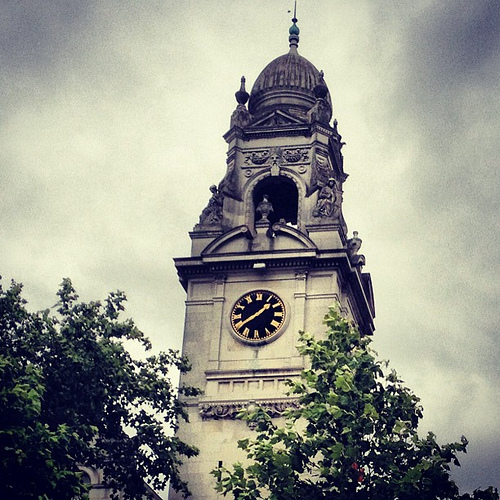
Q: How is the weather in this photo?
A: It is cloudy.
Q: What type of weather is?
A: It is cloudy.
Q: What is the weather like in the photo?
A: It is cloudy.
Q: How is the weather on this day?
A: It is cloudy.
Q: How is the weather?
A: It is cloudy.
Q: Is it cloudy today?
A: Yes, it is cloudy.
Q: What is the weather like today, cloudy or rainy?
A: It is cloudy.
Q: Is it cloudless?
A: No, it is cloudy.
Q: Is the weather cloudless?
A: No, it is cloudy.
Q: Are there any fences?
A: No, there are no fences.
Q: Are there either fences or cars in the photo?
A: No, there are no fences or cars.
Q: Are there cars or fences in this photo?
A: No, there are no fences or cars.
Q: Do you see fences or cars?
A: No, there are no fences or cars.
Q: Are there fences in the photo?
A: No, there are no fences.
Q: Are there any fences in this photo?
A: No, there are no fences.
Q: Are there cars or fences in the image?
A: No, there are no fences or cars.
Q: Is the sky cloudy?
A: Yes, the sky is cloudy.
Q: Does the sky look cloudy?
A: Yes, the sky is cloudy.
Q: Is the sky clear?
A: No, the sky is cloudy.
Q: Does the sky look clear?
A: No, the sky is cloudy.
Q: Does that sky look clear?
A: No, the sky is cloudy.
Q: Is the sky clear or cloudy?
A: The sky is cloudy.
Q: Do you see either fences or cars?
A: No, there are no fences or cars.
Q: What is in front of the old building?
A: The tree is in front of the clock tower.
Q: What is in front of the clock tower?
A: The tree is in front of the clock tower.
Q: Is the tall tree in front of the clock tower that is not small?
A: Yes, the tree is in front of the clock tower.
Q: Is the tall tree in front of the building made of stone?
A: Yes, the tree is in front of the clock tower.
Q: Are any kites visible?
A: No, there are no kites.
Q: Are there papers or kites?
A: No, there are no kites or papers.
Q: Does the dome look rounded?
A: Yes, the dome is rounded.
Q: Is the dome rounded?
A: Yes, the dome is rounded.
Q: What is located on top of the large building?
A: The dome is on top of the clock tower.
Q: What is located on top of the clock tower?
A: The dome is on top of the clock tower.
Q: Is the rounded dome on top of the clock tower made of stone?
A: Yes, the dome is on top of the clock tower.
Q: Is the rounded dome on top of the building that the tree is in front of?
A: Yes, the dome is on top of the clock tower.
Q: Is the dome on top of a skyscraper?
A: No, the dome is on top of the clock tower.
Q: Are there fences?
A: No, there are no fences.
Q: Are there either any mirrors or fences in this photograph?
A: No, there are no fences or mirrors.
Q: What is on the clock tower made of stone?
A: The statue is on the clock tower.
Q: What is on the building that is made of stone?
A: The statue is on the clock tower.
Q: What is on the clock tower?
A: The statue is on the clock tower.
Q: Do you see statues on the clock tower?
A: Yes, there is a statue on the clock tower.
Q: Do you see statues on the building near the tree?
A: Yes, there is a statue on the clock tower.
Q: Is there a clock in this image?
A: Yes, there is a clock.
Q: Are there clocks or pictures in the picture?
A: Yes, there is a clock.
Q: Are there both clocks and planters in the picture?
A: No, there is a clock but no planters.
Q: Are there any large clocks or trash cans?
A: Yes, there is a large clock.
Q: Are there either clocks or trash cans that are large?
A: Yes, the clock is large.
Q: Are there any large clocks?
A: Yes, there is a large clock.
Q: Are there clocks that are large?
A: Yes, there is a clock that is large.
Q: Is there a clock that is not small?
A: Yes, there is a large clock.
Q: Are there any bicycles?
A: No, there are no bicycles.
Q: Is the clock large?
A: Yes, the clock is large.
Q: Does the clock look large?
A: Yes, the clock is large.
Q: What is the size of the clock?
A: The clock is large.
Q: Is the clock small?
A: No, the clock is large.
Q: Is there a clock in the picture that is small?
A: No, there is a clock but it is large.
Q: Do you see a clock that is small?
A: No, there is a clock but it is large.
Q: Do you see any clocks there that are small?
A: No, there is a clock but it is large.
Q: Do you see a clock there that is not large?
A: No, there is a clock but it is large.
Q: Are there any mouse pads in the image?
A: No, there are no mouse pads.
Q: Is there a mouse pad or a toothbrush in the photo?
A: No, there are no mouse pads or toothbrushes.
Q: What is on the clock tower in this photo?
A: The statue is on the clock tower.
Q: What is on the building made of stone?
A: The statue is on the clock tower.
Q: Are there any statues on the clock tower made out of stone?
A: Yes, there is a statue on the clock tower.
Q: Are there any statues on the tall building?
A: Yes, there is a statue on the clock tower.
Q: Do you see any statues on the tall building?
A: Yes, there is a statue on the clock tower.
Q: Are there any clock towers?
A: Yes, there is a clock tower.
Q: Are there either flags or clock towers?
A: Yes, there is a clock tower.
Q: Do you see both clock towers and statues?
A: Yes, there are both a clock tower and a statue.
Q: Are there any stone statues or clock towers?
A: Yes, there is a stone clock tower.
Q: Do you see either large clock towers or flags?
A: Yes, there is a large clock tower.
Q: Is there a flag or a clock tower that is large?
A: Yes, the clock tower is large.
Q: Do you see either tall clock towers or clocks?
A: Yes, there is a tall clock tower.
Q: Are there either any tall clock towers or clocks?
A: Yes, there is a tall clock tower.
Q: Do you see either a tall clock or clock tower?
A: Yes, there is a tall clock tower.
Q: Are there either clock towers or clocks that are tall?
A: Yes, the clock tower is tall.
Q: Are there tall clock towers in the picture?
A: Yes, there is a tall clock tower.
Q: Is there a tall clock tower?
A: Yes, there is a tall clock tower.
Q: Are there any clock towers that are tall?
A: Yes, there is a clock tower that is tall.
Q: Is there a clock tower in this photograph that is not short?
A: Yes, there is a tall clock tower.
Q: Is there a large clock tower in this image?
A: Yes, there is a large clock tower.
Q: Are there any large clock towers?
A: Yes, there is a large clock tower.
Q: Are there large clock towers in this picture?
A: Yes, there is a large clock tower.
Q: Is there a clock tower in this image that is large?
A: Yes, there is a large clock tower.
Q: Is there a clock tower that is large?
A: Yes, there is a clock tower that is large.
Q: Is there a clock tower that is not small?
A: Yes, there is a large clock tower.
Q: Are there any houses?
A: No, there are no houses.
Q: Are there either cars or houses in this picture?
A: No, there are no houses or cars.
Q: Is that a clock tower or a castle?
A: That is a clock tower.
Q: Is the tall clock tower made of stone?
A: Yes, the clock tower is made of stone.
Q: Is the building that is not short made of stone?
A: Yes, the clock tower is made of stone.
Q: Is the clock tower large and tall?
A: Yes, the clock tower is large and tall.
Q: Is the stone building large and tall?
A: Yes, the clock tower is large and tall.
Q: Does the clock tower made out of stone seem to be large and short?
A: No, the clock tower is large but tall.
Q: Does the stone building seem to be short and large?
A: No, the clock tower is large but tall.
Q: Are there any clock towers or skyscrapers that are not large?
A: No, there is a clock tower but it is large.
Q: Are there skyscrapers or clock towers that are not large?
A: No, there is a clock tower but it is large.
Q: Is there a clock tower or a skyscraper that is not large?
A: No, there is a clock tower but it is large.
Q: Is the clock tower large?
A: Yes, the clock tower is large.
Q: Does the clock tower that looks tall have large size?
A: Yes, the clock tower is large.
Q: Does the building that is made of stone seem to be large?
A: Yes, the clock tower is large.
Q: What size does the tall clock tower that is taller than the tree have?
A: The clock tower has large size.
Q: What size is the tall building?
A: The clock tower is large.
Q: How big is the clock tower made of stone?
A: The clock tower is large.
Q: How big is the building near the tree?
A: The clock tower is large.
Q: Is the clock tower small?
A: No, the clock tower is large.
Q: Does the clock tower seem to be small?
A: No, the clock tower is large.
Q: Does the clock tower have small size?
A: No, the clock tower is large.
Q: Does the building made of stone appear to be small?
A: No, the clock tower is large.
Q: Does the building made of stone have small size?
A: No, the clock tower is large.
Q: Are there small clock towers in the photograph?
A: No, there is a clock tower but it is large.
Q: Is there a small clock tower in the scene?
A: No, there is a clock tower but it is large.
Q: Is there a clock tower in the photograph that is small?
A: No, there is a clock tower but it is large.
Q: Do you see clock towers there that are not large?
A: No, there is a clock tower but it is large.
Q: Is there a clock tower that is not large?
A: No, there is a clock tower but it is large.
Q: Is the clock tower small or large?
A: The clock tower is large.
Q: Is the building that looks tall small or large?
A: The clock tower is large.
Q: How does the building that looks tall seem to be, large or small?
A: The clock tower is large.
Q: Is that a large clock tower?
A: Yes, that is a large clock tower.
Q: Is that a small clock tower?
A: No, that is a large clock tower.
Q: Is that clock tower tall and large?
A: Yes, the clock tower is tall and large.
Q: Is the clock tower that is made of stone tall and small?
A: No, the clock tower is tall but large.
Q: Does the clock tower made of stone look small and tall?
A: No, the clock tower is tall but large.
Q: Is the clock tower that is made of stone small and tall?
A: No, the clock tower is tall but large.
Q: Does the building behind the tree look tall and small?
A: No, the clock tower is tall but large.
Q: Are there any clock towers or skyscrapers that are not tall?
A: No, there is a clock tower but it is tall.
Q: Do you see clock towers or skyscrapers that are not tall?
A: No, there is a clock tower but it is tall.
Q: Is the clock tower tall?
A: Yes, the clock tower is tall.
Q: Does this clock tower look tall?
A: Yes, the clock tower is tall.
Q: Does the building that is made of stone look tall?
A: Yes, the clock tower is tall.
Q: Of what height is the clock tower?
A: The clock tower is tall.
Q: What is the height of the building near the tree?
A: The clock tower is tall.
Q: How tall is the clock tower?
A: The clock tower is tall.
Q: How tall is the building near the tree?
A: The clock tower is tall.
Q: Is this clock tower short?
A: No, the clock tower is tall.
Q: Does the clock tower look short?
A: No, the clock tower is tall.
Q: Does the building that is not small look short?
A: No, the clock tower is tall.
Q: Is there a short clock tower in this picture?
A: No, there is a clock tower but it is tall.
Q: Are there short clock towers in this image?
A: No, there is a clock tower but it is tall.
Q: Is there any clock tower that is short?
A: No, there is a clock tower but it is tall.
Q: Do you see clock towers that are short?
A: No, there is a clock tower but it is tall.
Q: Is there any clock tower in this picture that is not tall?
A: No, there is a clock tower but it is tall.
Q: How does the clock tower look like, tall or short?
A: The clock tower is tall.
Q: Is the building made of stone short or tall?
A: The clock tower is tall.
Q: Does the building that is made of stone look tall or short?
A: The clock tower is tall.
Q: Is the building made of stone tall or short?
A: The clock tower is tall.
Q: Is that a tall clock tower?
A: Yes, that is a tall clock tower.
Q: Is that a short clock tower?
A: No, that is a tall clock tower.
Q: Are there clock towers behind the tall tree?
A: Yes, there is a clock tower behind the tree.